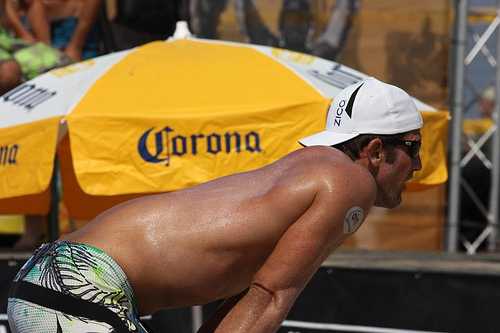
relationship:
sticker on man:
[342, 204, 362, 236] [3, 75, 430, 331]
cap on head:
[292, 77, 426, 150] [323, 69, 427, 213]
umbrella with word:
[2, 15, 457, 225] [138, 123, 263, 162]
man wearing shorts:
[3, 75, 430, 331] [0, 240, 142, 332]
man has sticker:
[3, 75, 430, 331] [338, 202, 366, 243]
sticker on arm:
[338, 202, 366, 243] [245, 172, 384, 332]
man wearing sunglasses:
[73, 140, 408, 331] [381, 135, 427, 156]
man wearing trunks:
[3, 75, 430, 331] [7, 238, 140, 330]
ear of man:
[365, 137, 382, 171] [3, 75, 430, 331]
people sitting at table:
[2, 0, 107, 67] [0, 44, 100, 60]